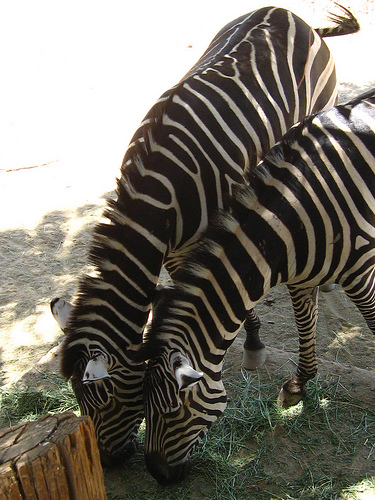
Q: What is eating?
A: Zebras.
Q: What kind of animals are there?
A: Zebras.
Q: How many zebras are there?
A: Two.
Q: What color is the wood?
A: Brown.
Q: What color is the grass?
A: Green.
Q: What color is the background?
A: White.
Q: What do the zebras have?
A: Stripes.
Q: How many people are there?
A: None.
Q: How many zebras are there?
A: Two.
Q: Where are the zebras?
A: On the grass and dirt.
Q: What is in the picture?
A: 2 zebras.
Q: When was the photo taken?
A: Daylight.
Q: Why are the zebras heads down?
A: They are eating.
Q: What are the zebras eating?
A: Grass.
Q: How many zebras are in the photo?
A: 2.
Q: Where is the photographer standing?
A: In front of the zebras.